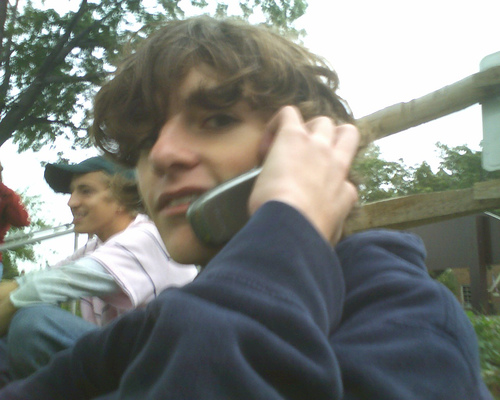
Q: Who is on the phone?
A: The guy.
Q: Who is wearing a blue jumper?
A: The man.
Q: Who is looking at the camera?
A: The guy.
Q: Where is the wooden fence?
A: Behind the man.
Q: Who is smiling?
A: The guy on the left.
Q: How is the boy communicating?
A: Cell phone.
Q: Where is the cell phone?
A: In the boy's hand.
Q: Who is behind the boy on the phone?
A: A boy in a baseball jersey.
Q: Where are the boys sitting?
A: Bleachers.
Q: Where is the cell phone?
A: Against the boy in blue's ear.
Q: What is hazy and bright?
A: The sky.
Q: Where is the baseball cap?
A: On the boy wearing the jersey.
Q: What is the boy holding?
A: Phone.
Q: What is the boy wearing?
A: Blue hoodie.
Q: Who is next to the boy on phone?
A: Boy with green cap.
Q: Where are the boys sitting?
A: Ground.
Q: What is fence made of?
A: Wood.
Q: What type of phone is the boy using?
A: Flip.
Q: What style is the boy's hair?
A: Long and curly.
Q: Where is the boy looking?
A: At camera.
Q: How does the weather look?
A: Cold and overcast.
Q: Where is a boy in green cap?
A: Next to boy on phone.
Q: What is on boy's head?
A: Hat.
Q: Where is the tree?
A: In the distance.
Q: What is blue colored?
A: Hoodie.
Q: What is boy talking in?
A: Phone.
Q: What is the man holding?
A: A phone.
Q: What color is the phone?
A: Silver.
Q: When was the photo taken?
A: Day time.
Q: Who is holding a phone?
A: A man.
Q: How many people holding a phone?
A: One.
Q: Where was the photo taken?
A: At a park.